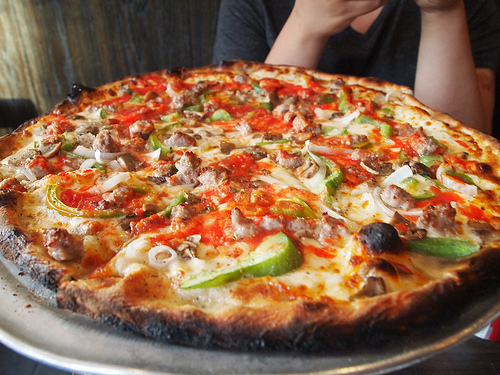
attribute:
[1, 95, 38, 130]
shadow — dark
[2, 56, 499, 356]
pizza — multi topping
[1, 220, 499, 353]
crust — burnt